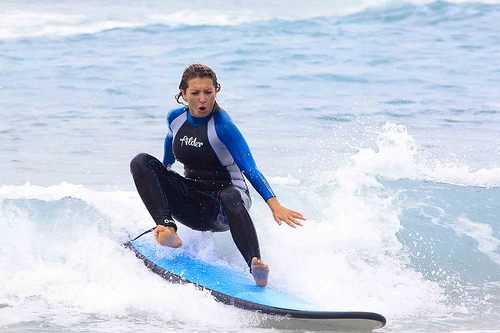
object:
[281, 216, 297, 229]
finger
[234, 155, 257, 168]
elbow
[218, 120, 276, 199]
arm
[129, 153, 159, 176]
knee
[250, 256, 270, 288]
foot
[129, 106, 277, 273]
wetsuit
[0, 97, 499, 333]
wave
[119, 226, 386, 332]
surfboard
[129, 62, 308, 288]
surfer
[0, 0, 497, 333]
ocean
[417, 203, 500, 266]
foam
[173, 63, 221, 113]
hair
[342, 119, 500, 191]
splash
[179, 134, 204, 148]
writing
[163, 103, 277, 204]
shirt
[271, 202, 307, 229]
hand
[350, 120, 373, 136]
part